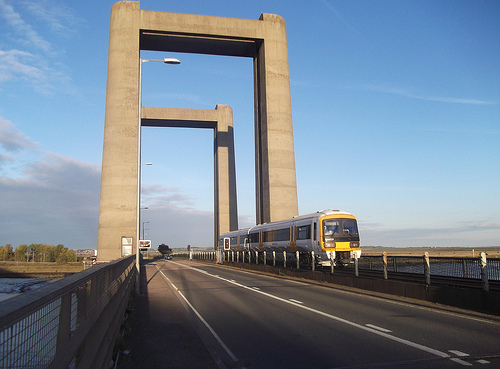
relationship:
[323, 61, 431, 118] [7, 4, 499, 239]
clouds on sky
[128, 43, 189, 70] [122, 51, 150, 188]
light on pole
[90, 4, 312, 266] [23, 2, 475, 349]
arch on bridge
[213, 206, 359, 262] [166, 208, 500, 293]
train on railroad